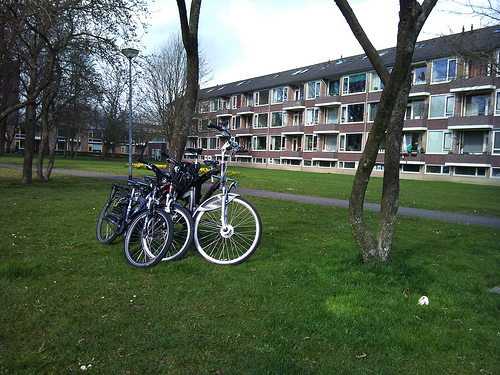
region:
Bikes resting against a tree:
[102, 130, 264, 271]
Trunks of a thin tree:
[347, 63, 404, 265]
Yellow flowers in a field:
[128, 156, 242, 173]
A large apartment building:
[181, 24, 498, 177]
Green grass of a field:
[0, 167, 496, 369]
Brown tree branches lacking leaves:
[4, 3, 104, 124]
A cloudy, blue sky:
[16, 2, 495, 116]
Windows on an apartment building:
[342, 74, 367, 128]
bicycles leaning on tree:
[95, 115, 270, 276]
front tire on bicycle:
[191, 191, 265, 269]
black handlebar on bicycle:
[201, 114, 258, 164]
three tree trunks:
[329, 1, 454, 275]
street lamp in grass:
[112, 36, 157, 193]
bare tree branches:
[3, 3, 153, 137]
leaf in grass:
[410, 288, 437, 320]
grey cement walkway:
[3, 160, 494, 247]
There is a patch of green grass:
[268, 294, 280, 366]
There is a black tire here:
[223, 197, 278, 338]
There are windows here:
[271, 135, 286, 193]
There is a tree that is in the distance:
[56, 123, 76, 131]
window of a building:
[250, 83, 281, 110]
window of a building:
[259, 109, 279, 139]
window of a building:
[252, 125, 277, 150]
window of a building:
[340, 68, 374, 93]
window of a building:
[342, 99, 369, 130]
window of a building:
[343, 125, 371, 155]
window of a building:
[430, 61, 461, 83]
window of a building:
[429, 89, 453, 127]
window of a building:
[430, 119, 455, 151]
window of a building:
[462, 92, 490, 122]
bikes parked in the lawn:
[96, 131, 266, 290]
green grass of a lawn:
[171, 272, 303, 363]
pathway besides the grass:
[256, 172, 353, 226]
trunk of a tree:
[333, 3, 426, 250]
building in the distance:
[223, 62, 375, 179]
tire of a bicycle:
[197, 196, 260, 267]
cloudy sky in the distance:
[212, 13, 324, 55]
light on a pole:
[114, 41, 148, 183]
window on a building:
[430, 49, 464, 94]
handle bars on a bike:
[131, 157, 187, 186]